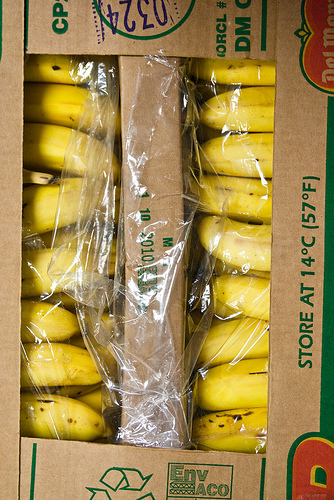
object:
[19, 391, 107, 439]
bananas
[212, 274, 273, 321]
banana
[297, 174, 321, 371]
instructions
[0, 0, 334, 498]
box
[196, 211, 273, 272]
bananas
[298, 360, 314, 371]
lettering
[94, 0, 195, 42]
circle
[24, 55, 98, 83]
bananas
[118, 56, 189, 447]
box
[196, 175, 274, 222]
bananas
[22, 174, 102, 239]
bananas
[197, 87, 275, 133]
bananas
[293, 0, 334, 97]
logo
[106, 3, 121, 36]
numbers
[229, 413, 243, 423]
spot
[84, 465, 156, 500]
sign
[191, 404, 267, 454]
banana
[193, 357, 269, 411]
banana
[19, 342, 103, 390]
banana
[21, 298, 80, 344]
banana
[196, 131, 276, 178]
banana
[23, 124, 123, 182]
bananas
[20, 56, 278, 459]
wrap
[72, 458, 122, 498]
symbol